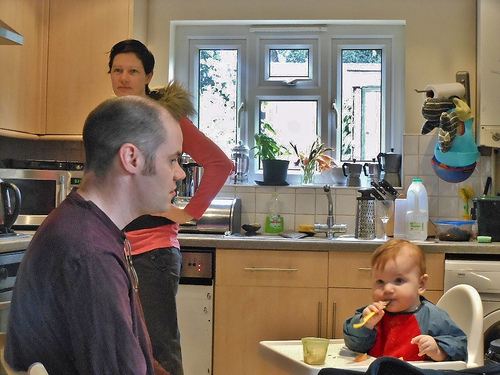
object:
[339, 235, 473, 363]
baby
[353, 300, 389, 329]
spoon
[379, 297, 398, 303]
mouth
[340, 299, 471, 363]
shirt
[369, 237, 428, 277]
hair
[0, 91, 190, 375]
man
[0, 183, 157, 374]
shirt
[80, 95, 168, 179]
hair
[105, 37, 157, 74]
hair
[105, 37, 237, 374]
woman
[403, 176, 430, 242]
container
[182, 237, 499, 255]
counter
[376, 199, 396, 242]
glass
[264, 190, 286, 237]
dishwashing liquid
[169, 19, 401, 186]
window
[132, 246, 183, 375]
pants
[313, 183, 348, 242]
faucet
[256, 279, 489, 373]
highchair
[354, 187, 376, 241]
cheese grater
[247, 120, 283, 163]
potted plant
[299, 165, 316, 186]
vase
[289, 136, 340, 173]
flowers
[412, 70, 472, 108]
paper towel holder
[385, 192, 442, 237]
knife block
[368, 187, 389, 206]
knives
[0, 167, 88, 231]
microwave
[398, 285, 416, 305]
cheeks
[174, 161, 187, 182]
nose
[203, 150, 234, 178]
elbow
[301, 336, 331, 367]
cup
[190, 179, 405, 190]
window sill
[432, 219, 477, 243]
bowl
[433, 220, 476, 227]
lid